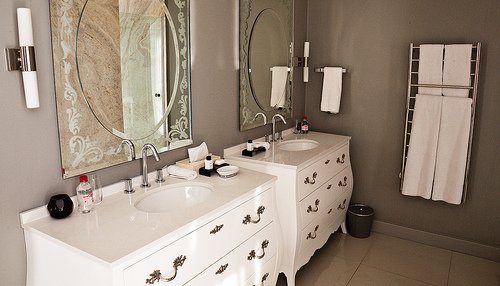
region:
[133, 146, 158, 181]
silver faucet to sink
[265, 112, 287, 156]
silver faucet to sink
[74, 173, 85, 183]
red cap on a bottle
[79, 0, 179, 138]
large oval mirror on the wall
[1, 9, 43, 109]
white lamp on the wall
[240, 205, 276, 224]
silver handle on drawer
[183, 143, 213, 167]
white kleenex from box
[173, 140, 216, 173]
tissues in a box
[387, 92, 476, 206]
white towels hanging down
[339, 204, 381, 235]
black trash can on floor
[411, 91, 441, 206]
the towels are hanging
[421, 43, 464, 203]
towels are white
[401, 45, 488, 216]
the metal towel rack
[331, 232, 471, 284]
the floor is tiled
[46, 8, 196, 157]
the mirror on the wall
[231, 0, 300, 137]
the mirror on the wall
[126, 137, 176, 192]
faucet above the sink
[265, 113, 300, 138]
faucet above the sink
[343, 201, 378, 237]
waste bin on the floor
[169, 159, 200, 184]
box of tissues on sink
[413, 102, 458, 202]
white towels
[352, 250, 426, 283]
the floor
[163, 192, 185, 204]
the sink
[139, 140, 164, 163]
the faucet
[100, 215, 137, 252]
the counter is white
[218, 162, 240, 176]
a soap dish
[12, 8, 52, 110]
a light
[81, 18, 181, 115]
a mirror on the wall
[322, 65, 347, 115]
a small white towel hanging up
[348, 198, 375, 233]
a trash can on the floor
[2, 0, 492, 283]
A bathroom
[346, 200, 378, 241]
A small dark colored waste bin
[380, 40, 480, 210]
A silver long towel rack hanging on the wall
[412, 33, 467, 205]
Four white towels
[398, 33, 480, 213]
Towels hanging on a towel rack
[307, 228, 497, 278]
Large grey tiles on the floor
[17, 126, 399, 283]
Two matching sinks beside each other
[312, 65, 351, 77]
A silver towel holder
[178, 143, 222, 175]
A box of tissues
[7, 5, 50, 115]
A long white and silver light fixture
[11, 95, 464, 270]
there are two sinks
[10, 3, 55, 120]
this is a bathroom light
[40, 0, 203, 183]
a glass mirror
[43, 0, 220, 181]
the mirror has an embossed pattern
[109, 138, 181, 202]
this is the faucet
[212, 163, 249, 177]
a white soap dish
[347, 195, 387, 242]
a small garbage pail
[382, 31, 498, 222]
an aluminum towel rack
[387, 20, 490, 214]
there are four towels hanging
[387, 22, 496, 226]
the towels are white